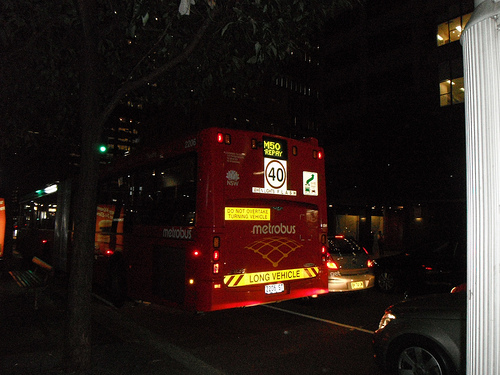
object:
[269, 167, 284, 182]
number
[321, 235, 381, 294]
car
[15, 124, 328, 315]
firetruck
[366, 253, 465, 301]
car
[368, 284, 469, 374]
car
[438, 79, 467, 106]
light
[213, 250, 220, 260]
light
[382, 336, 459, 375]
tire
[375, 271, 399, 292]
tire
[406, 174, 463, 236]
ground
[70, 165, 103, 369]
tree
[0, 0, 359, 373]
tree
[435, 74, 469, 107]
window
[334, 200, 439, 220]
lights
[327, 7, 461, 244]
building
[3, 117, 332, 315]
bus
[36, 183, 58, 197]
white light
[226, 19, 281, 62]
green leaves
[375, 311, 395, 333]
headlight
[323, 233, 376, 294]
car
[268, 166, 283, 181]
forty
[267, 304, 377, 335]
road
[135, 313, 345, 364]
road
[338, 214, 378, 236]
entrance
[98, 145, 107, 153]
light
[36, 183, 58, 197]
light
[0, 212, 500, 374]
street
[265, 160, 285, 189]
circle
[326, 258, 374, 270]
tail lights